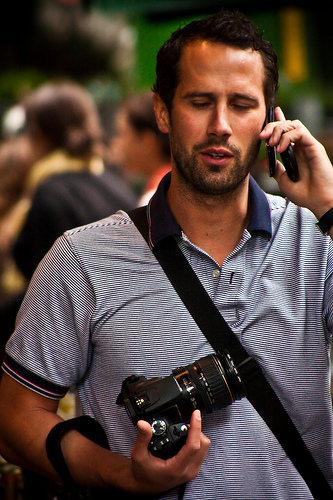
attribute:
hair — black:
[150, 9, 278, 124]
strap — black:
[126, 201, 322, 492]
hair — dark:
[150, 10, 279, 114]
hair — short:
[154, 16, 282, 105]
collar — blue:
[144, 171, 182, 245]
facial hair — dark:
[169, 139, 260, 192]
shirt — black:
[5, 168, 139, 257]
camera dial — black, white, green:
[148, 418, 166, 435]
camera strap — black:
[43, 413, 114, 498]